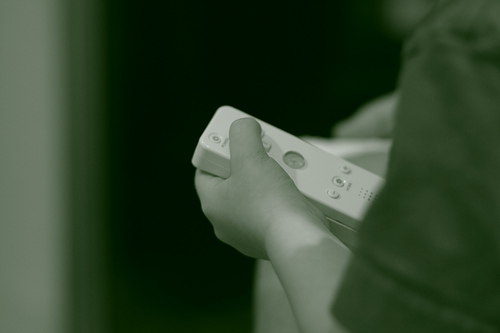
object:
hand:
[193, 117, 330, 259]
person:
[330, 0, 500, 333]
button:
[208, 130, 221, 142]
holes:
[358, 188, 378, 201]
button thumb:
[229, 117, 271, 160]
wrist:
[263, 213, 352, 282]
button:
[282, 150, 306, 168]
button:
[332, 176, 345, 187]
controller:
[190, 105, 386, 249]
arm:
[267, 56, 500, 332]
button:
[210, 134, 222, 143]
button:
[262, 139, 272, 152]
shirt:
[327, 0, 500, 333]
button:
[340, 164, 351, 174]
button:
[328, 189, 339, 198]